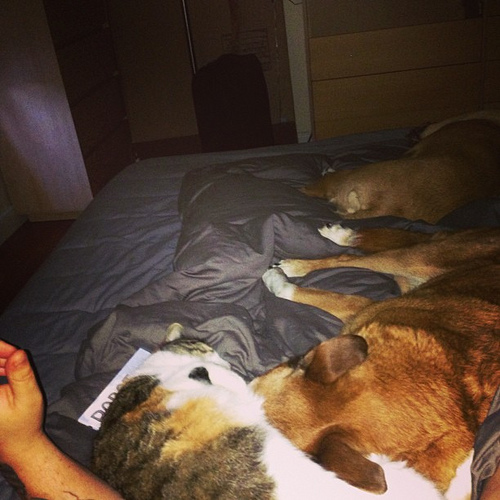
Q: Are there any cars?
A: No, there are no cars.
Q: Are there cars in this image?
A: No, there are no cars.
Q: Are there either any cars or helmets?
A: No, there are no cars or helmets.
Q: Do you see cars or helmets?
A: No, there are no cars or helmets.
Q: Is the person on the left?
A: Yes, the person is on the left of the image.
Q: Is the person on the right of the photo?
A: No, the person is on the left of the image.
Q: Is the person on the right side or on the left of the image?
A: The person is on the left of the image.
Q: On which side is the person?
A: The person is on the left of the image.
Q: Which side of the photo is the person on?
A: The person is on the left of the image.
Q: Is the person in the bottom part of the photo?
A: Yes, the person is in the bottom of the image.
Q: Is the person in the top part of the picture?
A: No, the person is in the bottom of the image.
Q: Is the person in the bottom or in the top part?
A: The person is in the bottom of the image.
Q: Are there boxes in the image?
A: No, there are no boxes.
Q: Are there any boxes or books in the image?
A: No, there are no boxes or books.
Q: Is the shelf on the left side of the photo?
A: Yes, the shelf is on the left of the image.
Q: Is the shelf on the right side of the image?
A: No, the shelf is on the left of the image.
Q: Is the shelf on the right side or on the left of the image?
A: The shelf is on the left of the image.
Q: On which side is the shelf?
A: The shelf is on the left of the image.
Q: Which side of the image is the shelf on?
A: The shelf is on the left of the image.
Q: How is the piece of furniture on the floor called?
A: The piece of furniture is a shelf.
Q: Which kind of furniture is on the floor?
A: The piece of furniture is a shelf.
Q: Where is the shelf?
A: The shelf is on the floor.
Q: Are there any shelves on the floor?
A: Yes, there is a shelf on the floor.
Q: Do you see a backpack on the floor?
A: No, there is a shelf on the floor.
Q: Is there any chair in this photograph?
A: No, there are no chairs.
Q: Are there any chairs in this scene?
A: No, there are no chairs.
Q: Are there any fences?
A: No, there are no fences.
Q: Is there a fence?
A: No, there are no fences.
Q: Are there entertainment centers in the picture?
A: No, there are no entertainment centers.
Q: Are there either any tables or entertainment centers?
A: No, there are no entertainment centers or tables.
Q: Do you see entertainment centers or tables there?
A: No, there are no entertainment centers or tables.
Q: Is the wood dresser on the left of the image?
A: Yes, the dresser is on the left of the image.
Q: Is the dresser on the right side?
A: No, the dresser is on the left of the image.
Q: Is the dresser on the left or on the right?
A: The dresser is on the left of the image.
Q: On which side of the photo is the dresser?
A: The dresser is on the left of the image.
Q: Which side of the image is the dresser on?
A: The dresser is on the left of the image.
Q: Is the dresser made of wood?
A: Yes, the dresser is made of wood.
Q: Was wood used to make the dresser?
A: Yes, the dresser is made of wood.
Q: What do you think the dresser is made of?
A: The dresser is made of wood.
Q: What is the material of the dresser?
A: The dresser is made of wood.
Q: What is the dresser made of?
A: The dresser is made of wood.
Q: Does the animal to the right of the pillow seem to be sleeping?
A: Yes, the animal is sleeping.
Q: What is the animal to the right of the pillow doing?
A: The animal is sleeping.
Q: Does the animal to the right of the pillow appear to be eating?
A: No, the animal is sleeping.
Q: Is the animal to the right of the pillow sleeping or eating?
A: The animal is sleeping.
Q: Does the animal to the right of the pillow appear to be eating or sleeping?
A: The animal is sleeping.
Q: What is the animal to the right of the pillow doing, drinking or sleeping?
A: The animal is sleeping.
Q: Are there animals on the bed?
A: Yes, there is an animal on the bed.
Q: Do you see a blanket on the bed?
A: No, there is an animal on the bed.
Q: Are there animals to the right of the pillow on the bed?
A: Yes, there is an animal to the right of the pillow.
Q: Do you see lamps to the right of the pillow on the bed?
A: No, there is an animal to the right of the pillow.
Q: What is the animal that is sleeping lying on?
A: The animal is lying on the bed.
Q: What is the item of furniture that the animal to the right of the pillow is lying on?
A: The piece of furniture is a bed.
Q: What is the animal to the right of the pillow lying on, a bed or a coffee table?
A: The animal is lying on a bed.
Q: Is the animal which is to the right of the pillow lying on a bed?
A: Yes, the animal is lying on a bed.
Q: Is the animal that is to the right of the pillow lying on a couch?
A: No, the animal is lying on a bed.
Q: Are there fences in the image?
A: No, there are no fences.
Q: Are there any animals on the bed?
A: Yes, there is an animal on the bed.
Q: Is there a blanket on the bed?
A: No, there is an animal on the bed.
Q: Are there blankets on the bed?
A: No, there is an animal on the bed.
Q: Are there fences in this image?
A: No, there are no fences.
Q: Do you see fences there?
A: No, there are no fences.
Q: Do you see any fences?
A: No, there are no fences.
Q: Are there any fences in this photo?
A: No, there are no fences.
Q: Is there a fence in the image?
A: No, there are no fences.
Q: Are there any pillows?
A: Yes, there is a pillow.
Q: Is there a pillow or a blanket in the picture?
A: Yes, there is a pillow.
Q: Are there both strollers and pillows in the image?
A: No, there is a pillow but no strollers.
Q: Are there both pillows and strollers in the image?
A: No, there is a pillow but no strollers.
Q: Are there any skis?
A: No, there are no skis.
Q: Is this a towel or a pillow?
A: This is a pillow.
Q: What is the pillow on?
A: The pillow is on the bed.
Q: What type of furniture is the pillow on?
A: The pillow is on the bed.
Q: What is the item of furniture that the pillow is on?
A: The piece of furniture is a bed.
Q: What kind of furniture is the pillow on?
A: The pillow is on the bed.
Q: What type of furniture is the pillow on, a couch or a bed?
A: The pillow is on a bed.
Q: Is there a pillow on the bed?
A: Yes, there is a pillow on the bed.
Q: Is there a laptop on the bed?
A: No, there is a pillow on the bed.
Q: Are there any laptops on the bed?
A: No, there is a pillow on the bed.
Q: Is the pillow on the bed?
A: Yes, the pillow is on the bed.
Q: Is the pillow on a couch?
A: No, the pillow is on the bed.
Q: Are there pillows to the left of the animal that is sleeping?
A: Yes, there is a pillow to the left of the animal.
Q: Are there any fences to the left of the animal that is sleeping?
A: No, there is a pillow to the left of the animal.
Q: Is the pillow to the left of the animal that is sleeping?
A: Yes, the pillow is to the left of the animal.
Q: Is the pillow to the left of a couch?
A: No, the pillow is to the left of the animal.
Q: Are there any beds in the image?
A: Yes, there is a bed.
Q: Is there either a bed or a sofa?
A: Yes, there is a bed.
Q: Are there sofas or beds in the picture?
A: Yes, there is a bed.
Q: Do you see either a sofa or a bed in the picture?
A: Yes, there is a bed.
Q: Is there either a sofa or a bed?
A: Yes, there is a bed.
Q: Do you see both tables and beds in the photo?
A: No, there is a bed but no tables.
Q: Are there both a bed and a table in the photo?
A: No, there is a bed but no tables.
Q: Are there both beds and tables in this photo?
A: No, there is a bed but no tables.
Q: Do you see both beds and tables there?
A: No, there is a bed but no tables.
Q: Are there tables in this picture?
A: No, there are no tables.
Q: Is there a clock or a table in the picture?
A: No, there are no tables or clocks.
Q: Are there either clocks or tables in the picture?
A: No, there are no tables or clocks.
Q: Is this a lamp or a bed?
A: This is a bed.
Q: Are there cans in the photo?
A: No, there are no cans.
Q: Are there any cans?
A: No, there are no cans.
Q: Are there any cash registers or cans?
A: No, there are no cans or cash registers.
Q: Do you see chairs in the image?
A: No, there are no chairs.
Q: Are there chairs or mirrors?
A: No, there are no chairs or mirrors.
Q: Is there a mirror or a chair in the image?
A: No, there are no chairs or mirrors.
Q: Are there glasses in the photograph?
A: No, there are no glasses.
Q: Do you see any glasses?
A: No, there are no glasses.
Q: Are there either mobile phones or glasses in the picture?
A: No, there are no glasses or mobile phones.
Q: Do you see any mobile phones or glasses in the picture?
A: No, there are no glasses or mobile phones.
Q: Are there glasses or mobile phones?
A: No, there are no glasses or mobile phones.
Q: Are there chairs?
A: No, there are no chairs.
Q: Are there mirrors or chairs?
A: No, there are no chairs or mirrors.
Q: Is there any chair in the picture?
A: No, there are no chairs.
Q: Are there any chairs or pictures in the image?
A: No, there are no chairs or pictures.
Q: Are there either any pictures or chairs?
A: No, there are no chairs or pictures.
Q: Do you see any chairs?
A: No, there are no chairs.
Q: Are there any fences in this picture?
A: No, there are no fences.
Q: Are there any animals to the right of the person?
A: Yes, there is an animal to the right of the person.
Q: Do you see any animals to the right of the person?
A: Yes, there is an animal to the right of the person.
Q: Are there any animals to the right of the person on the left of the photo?
A: Yes, there is an animal to the right of the person.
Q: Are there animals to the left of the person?
A: No, the animal is to the right of the person.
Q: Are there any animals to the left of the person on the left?
A: No, the animal is to the right of the person.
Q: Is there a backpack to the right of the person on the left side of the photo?
A: No, there is an animal to the right of the person.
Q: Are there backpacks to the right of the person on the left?
A: No, there is an animal to the right of the person.